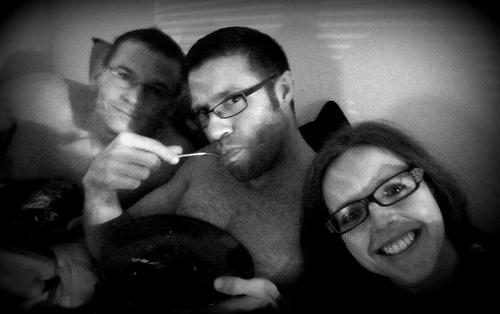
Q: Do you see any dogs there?
A: No, there are no dogs.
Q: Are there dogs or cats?
A: No, there are no dogs or cats.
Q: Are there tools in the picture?
A: No, there are no tools.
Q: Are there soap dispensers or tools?
A: No, there are no tools or soap dispensers.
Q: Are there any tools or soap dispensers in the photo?
A: No, there are no tools or soap dispensers.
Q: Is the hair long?
A: Yes, the hair is long.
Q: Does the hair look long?
A: Yes, the hair is long.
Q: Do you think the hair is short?
A: No, the hair is long.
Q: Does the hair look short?
A: No, the hair is long.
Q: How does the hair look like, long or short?
A: The hair is long.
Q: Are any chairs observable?
A: No, there are no chairs.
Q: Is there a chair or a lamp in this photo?
A: No, there are no chairs or lamps.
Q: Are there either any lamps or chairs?
A: No, there are no chairs or lamps.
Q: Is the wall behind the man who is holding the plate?
A: Yes, the wall is behind the man.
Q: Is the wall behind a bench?
A: No, the wall is behind the man.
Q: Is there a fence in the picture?
A: No, there are no fences.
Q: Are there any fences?
A: No, there are no fences.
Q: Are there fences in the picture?
A: No, there are no fences.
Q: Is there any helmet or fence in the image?
A: No, there are no fences or helmets.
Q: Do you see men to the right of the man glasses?
A: No, the man is to the left of the glasses.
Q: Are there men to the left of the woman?
A: Yes, there is a man to the left of the woman.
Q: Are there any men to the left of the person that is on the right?
A: Yes, there is a man to the left of the woman.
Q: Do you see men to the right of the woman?
A: No, the man is to the left of the woman.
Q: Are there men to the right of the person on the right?
A: No, the man is to the left of the woman.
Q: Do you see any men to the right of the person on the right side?
A: No, the man is to the left of the woman.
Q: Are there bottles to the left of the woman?
A: No, there is a man to the left of the woman.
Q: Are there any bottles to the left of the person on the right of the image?
A: No, there is a man to the left of the woman.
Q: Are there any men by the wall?
A: Yes, there is a man by the wall.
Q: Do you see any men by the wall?
A: Yes, there is a man by the wall.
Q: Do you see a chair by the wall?
A: No, there is a man by the wall.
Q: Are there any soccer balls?
A: No, there are no soccer balls.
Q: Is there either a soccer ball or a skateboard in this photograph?
A: No, there are no soccer balls or skateboards.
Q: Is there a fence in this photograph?
A: No, there are no fences.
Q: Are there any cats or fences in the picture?
A: No, there are no fences or cats.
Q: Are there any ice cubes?
A: No, there are no ice cubes.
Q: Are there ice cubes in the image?
A: No, there are no ice cubes.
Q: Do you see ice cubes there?
A: No, there are no ice cubes.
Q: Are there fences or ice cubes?
A: No, there are no ice cubes or fences.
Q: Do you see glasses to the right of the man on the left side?
A: Yes, there are glasses to the right of the man.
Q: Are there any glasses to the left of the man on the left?
A: No, the glasses are to the right of the man.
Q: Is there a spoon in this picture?
A: Yes, there is a spoon.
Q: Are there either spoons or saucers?
A: Yes, there is a spoon.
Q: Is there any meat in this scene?
A: No, there is no meat.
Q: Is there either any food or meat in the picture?
A: No, there are no meat or food.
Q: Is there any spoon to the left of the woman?
A: Yes, there is a spoon to the left of the woman.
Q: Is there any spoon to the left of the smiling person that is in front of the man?
A: Yes, there is a spoon to the left of the woman.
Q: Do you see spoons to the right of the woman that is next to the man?
A: No, the spoon is to the left of the woman.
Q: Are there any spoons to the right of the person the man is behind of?
A: No, the spoon is to the left of the woman.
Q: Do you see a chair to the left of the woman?
A: No, there is a spoon to the left of the woman.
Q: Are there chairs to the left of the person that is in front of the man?
A: No, there is a spoon to the left of the woman.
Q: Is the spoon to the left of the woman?
A: Yes, the spoon is to the left of the woman.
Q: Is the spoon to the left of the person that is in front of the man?
A: Yes, the spoon is to the left of the woman.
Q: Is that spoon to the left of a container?
A: No, the spoon is to the left of the woman.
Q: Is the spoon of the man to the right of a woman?
A: No, the spoon is to the left of a woman.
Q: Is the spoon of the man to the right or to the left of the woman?
A: The spoon is to the left of the woman.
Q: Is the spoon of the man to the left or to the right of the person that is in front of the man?
A: The spoon is to the left of the woman.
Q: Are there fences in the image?
A: No, there are no fences.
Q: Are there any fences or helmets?
A: No, there are no fences or helmets.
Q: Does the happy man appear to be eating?
A: Yes, the man is eating.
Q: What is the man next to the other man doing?
A: The man is eating.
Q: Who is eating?
A: The man is eating.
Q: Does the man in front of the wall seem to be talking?
A: No, the man is eating.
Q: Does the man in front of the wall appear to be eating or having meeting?
A: The man is eating.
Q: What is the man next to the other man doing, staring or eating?
A: The man is eating.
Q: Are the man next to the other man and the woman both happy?
A: Yes, both the man and the woman are happy.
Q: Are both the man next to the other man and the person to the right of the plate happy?
A: Yes, both the man and the woman are happy.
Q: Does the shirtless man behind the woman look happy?
A: Yes, the man is happy.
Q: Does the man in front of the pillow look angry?
A: No, the man is happy.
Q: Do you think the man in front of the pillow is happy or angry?
A: The man is happy.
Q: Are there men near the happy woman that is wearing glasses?
A: Yes, there is a man near the woman.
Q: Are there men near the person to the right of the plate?
A: Yes, there is a man near the woman.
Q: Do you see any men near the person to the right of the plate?
A: Yes, there is a man near the woman.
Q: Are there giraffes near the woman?
A: No, there is a man near the woman.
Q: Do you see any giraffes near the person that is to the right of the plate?
A: No, there is a man near the woman.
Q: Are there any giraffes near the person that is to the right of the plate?
A: No, there is a man near the woman.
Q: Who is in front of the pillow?
A: The man is in front of the pillow.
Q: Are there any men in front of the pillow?
A: Yes, there is a man in front of the pillow.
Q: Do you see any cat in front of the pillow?
A: No, there is a man in front of the pillow.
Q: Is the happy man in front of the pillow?
A: Yes, the man is in front of the pillow.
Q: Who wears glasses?
A: The man wears glasses.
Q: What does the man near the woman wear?
A: The man wears glasses.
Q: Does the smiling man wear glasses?
A: Yes, the man wears glasses.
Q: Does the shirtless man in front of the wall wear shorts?
A: No, the man wears glasses.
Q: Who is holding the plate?
A: The man is holding the plate.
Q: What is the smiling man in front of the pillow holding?
A: The man is holding the plate.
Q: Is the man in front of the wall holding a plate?
A: Yes, the man is holding a plate.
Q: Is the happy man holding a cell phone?
A: No, the man is holding a plate.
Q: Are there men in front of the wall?
A: Yes, there is a man in front of the wall.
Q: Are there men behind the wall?
A: No, the man is in front of the wall.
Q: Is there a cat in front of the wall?
A: No, there is a man in front of the wall.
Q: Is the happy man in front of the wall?
A: Yes, the man is in front of the wall.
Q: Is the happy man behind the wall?
A: No, the man is in front of the wall.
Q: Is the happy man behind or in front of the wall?
A: The man is in front of the wall.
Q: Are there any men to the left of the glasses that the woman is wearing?
A: Yes, there is a man to the left of the glasses.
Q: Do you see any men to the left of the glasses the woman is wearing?
A: Yes, there is a man to the left of the glasses.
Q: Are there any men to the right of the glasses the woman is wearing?
A: No, the man is to the left of the glasses.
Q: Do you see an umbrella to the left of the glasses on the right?
A: No, there is a man to the left of the glasses.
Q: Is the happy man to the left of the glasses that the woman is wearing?
A: Yes, the man is to the left of the glasses.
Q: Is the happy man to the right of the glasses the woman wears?
A: No, the man is to the left of the glasses.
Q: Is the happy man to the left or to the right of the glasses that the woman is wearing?
A: The man is to the left of the glasses.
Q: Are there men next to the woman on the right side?
A: Yes, there is a man next to the woman.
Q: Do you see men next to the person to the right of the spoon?
A: Yes, there is a man next to the woman.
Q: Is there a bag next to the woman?
A: No, there is a man next to the woman.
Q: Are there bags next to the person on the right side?
A: No, there is a man next to the woman.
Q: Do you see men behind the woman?
A: Yes, there is a man behind the woman.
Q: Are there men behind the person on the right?
A: Yes, there is a man behind the woman.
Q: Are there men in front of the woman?
A: No, the man is behind the woman.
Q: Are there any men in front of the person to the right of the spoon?
A: No, the man is behind the woman.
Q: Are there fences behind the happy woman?
A: No, there is a man behind the woman.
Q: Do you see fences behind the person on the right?
A: No, there is a man behind the woman.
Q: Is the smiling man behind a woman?
A: Yes, the man is behind a woman.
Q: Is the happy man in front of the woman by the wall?
A: No, the man is behind the woman.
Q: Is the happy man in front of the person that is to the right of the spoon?
A: No, the man is behind the woman.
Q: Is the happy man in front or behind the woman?
A: The man is behind the woman.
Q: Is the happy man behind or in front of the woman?
A: The man is behind the woman.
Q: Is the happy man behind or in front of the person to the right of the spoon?
A: The man is behind the woman.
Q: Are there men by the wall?
A: Yes, there is a man by the wall.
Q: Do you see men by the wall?
A: Yes, there is a man by the wall.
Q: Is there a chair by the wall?
A: No, there is a man by the wall.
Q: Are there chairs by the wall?
A: No, there is a man by the wall.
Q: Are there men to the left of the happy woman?
A: Yes, there is a man to the left of the woman.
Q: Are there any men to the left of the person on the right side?
A: Yes, there is a man to the left of the woman.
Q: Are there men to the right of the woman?
A: No, the man is to the left of the woman.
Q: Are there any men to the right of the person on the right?
A: No, the man is to the left of the woman.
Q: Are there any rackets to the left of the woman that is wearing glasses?
A: No, there is a man to the left of the woman.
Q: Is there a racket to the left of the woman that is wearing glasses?
A: No, there is a man to the left of the woman.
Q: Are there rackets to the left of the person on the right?
A: No, there is a man to the left of the woman.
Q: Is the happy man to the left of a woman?
A: Yes, the man is to the left of a woman.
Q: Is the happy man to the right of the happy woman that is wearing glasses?
A: No, the man is to the left of the woman.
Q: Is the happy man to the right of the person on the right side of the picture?
A: No, the man is to the left of the woman.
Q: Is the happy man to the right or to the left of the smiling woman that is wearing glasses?
A: The man is to the left of the woman.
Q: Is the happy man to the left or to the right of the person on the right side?
A: The man is to the left of the woman.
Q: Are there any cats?
A: No, there are no cats.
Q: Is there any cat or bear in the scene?
A: No, there are no cats or bears.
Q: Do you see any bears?
A: No, there are no bears.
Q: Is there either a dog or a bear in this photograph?
A: No, there are no bears or dogs.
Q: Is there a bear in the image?
A: No, there are no bears.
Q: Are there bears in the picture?
A: No, there are no bears.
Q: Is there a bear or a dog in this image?
A: No, there are no bears or dogs.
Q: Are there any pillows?
A: Yes, there is a pillow.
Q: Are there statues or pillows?
A: Yes, there is a pillow.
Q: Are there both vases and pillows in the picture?
A: No, there is a pillow but no vases.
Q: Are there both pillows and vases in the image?
A: No, there is a pillow but no vases.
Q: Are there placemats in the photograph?
A: No, there are no placemats.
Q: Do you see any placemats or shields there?
A: No, there are no placemats or shields.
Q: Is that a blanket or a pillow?
A: That is a pillow.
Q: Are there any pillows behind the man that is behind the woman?
A: Yes, there is a pillow behind the man.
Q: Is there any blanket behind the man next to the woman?
A: No, there is a pillow behind the man.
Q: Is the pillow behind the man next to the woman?
A: Yes, the pillow is behind the man.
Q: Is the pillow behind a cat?
A: No, the pillow is behind the man.